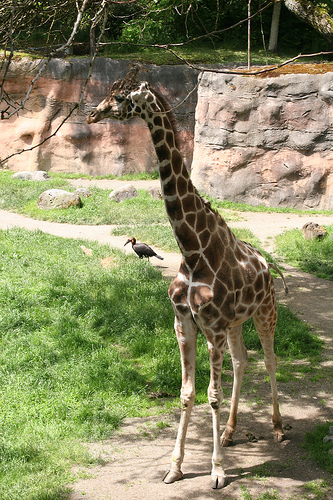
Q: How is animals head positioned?
A: Turned to its right.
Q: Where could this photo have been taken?
A: Zoo.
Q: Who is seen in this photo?
A: Noone.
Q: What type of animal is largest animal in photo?
A: Giraffe.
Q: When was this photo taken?
A: Daytime.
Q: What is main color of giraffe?
A: Brown.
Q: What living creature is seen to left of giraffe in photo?
A: Bird.